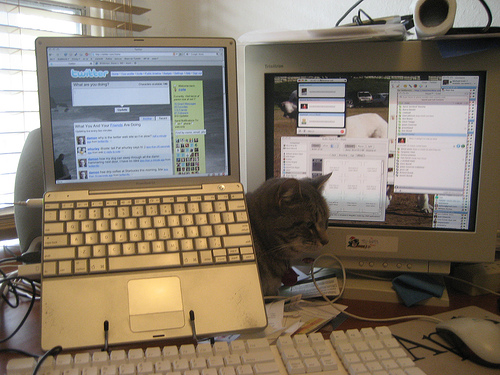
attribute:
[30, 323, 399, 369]
keyboard — white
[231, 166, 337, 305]
grey cat — grey 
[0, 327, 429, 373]
white keyboard — white 